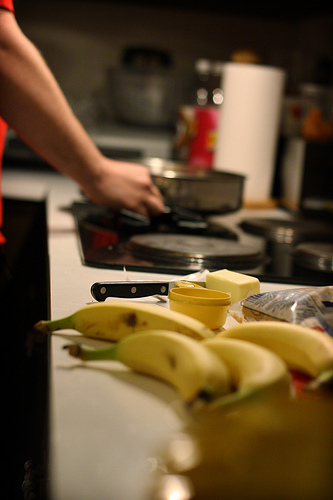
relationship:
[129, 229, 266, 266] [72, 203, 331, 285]
stove cover on stove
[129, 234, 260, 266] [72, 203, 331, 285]
stove cover on stove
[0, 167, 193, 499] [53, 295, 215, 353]
table has a banana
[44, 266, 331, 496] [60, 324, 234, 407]
table has another banana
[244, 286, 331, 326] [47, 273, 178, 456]
bag on top of table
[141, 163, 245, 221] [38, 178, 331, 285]
pot on stove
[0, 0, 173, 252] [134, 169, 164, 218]
person has fingers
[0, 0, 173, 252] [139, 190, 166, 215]
person has finger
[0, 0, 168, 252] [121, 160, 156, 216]
person has knuckles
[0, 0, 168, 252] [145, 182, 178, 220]
person has a finger